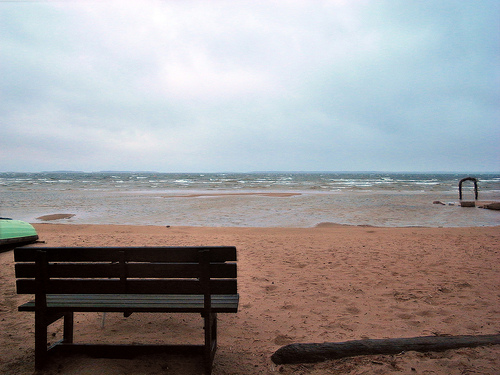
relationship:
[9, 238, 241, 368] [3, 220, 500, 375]
bench on beach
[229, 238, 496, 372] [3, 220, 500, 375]
footprints on beach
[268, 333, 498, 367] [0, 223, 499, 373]
wood on sand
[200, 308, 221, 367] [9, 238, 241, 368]
leg of bench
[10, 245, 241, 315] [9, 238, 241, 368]
back of bench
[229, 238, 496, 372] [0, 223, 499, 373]
footprints in sand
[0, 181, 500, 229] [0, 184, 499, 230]
water on far beach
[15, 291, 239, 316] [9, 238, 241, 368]
seat of bench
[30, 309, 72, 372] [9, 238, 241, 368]
left leg of bench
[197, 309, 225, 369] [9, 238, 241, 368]
right leg of bench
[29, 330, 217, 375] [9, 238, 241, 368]
shadow of bench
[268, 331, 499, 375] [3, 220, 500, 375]
log on beach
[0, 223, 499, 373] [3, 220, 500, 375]
sand on beach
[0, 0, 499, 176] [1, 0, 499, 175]
clouds in sky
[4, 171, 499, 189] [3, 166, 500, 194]
waves on ocean